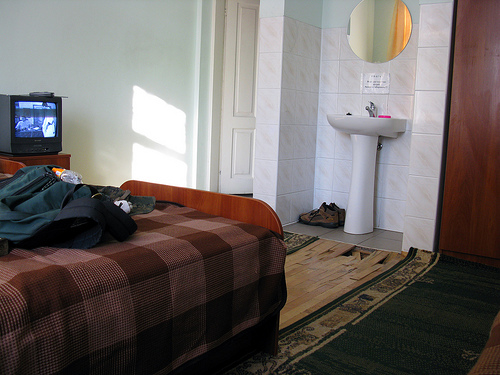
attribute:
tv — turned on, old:
[0, 95, 64, 157]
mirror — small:
[346, 0, 413, 65]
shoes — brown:
[297, 203, 346, 229]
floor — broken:
[189, 221, 499, 373]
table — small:
[2, 153, 72, 170]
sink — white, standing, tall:
[327, 103, 407, 235]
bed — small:
[0, 179, 288, 374]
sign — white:
[360, 70, 391, 95]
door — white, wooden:
[216, 0, 261, 199]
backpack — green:
[1, 165, 137, 254]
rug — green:
[203, 230, 499, 373]